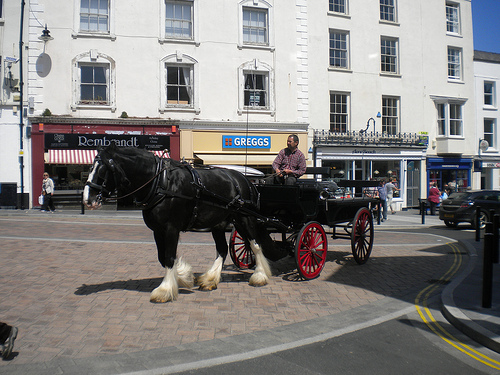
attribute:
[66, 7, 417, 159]
building — white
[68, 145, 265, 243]
horse — black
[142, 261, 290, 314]
hooves — white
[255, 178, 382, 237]
carriage — black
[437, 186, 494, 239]
car — black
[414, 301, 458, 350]
lines — yellow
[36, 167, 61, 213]
woman — walking, white